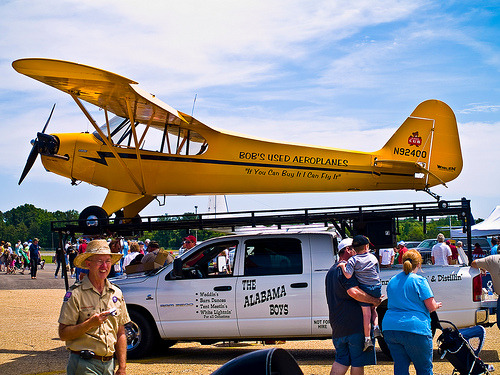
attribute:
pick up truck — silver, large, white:
[106, 227, 490, 360]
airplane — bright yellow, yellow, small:
[11, 58, 462, 228]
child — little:
[337, 235, 383, 351]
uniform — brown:
[59, 276, 131, 359]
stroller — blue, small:
[437, 316, 496, 375]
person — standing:
[28, 236, 43, 279]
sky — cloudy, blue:
[1, 1, 500, 220]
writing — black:
[239, 277, 289, 317]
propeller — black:
[15, 101, 58, 184]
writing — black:
[237, 151, 350, 169]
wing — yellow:
[12, 58, 222, 135]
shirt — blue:
[381, 269, 435, 336]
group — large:
[1, 238, 46, 280]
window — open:
[163, 239, 239, 281]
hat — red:
[184, 233, 197, 243]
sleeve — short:
[58, 289, 81, 326]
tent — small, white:
[448, 204, 499, 239]